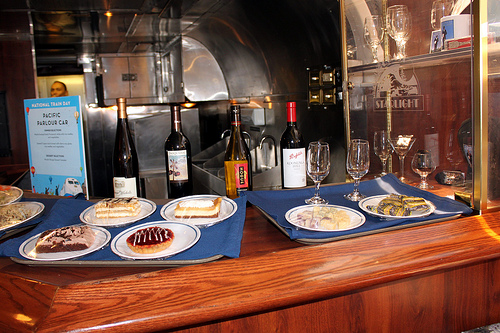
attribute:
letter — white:
[374, 97, 381, 109]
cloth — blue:
[197, 226, 245, 263]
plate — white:
[158, 192, 239, 227]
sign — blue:
[16, 91, 95, 201]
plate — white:
[109, 215, 201, 263]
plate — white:
[17, 223, 111, 262]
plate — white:
[221, 200, 233, 217]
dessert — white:
[174, 193, 231, 228]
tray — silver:
[11, 252, 223, 267]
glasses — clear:
[349, 133, 387, 219]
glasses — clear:
[280, 123, 358, 201]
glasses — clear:
[373, 124, 450, 216]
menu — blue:
[24, 100, 92, 195]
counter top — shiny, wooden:
[0, 174, 500, 330]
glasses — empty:
[355, 4, 453, 68]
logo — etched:
[374, 56, 423, 113]